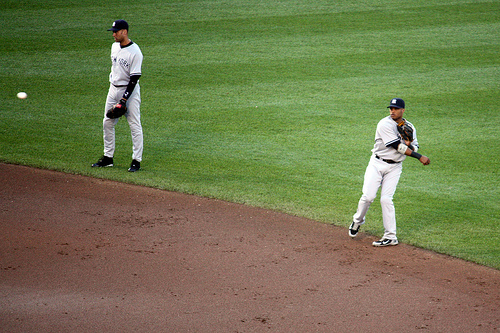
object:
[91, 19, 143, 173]
man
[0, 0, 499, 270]
grass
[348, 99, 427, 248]
man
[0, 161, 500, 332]
dirt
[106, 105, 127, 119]
glove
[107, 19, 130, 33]
cap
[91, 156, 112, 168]
shoes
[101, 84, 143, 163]
pants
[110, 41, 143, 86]
shirt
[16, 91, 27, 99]
baseball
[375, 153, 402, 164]
belt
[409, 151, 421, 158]
band